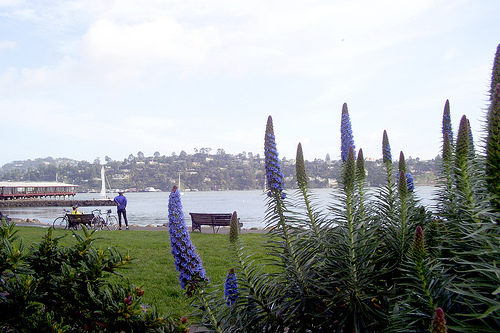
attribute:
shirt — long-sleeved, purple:
[112, 194, 129, 210]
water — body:
[0, 185, 457, 228]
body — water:
[0, 187, 449, 227]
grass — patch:
[1, 222, 312, 332]